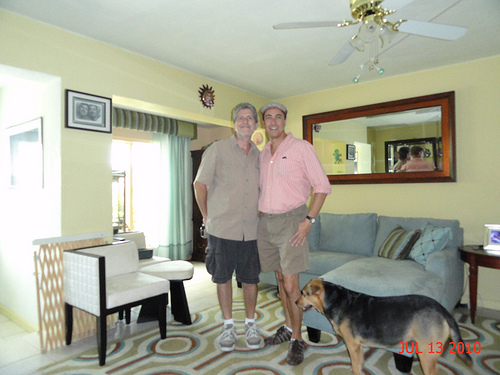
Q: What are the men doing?
A: Posing for a picture.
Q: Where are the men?
A: In a living room.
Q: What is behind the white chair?
A: A child gate.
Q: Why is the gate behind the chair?
A: To make the gate stand.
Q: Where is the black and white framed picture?
A: Hanging on the wall.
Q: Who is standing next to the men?
A: The dog.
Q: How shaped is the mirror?
A: Rectangular.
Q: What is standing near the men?
A: A dog.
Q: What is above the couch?
A: A framed mirror.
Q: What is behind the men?
A: A grey couch.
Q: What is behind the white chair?
A: A baby gate.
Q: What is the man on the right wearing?
A: A pink shirt and tan shorts.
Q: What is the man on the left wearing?
A: A tan shirt and dark brown shorts.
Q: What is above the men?
A: A ceiling fan.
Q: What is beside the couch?
A: An end table.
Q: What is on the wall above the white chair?
A: A framed picture.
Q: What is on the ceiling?
A: A fan.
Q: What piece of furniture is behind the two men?
A: A sofa.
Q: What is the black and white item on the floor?
A: A chair.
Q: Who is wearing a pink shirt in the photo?
A: A man.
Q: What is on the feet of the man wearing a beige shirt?
A: Sneakers.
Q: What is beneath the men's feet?
A: A carpet.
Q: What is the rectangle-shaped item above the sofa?
A: A mirror.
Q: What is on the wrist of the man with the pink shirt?
A: A watch.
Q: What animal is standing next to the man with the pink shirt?
A: A dog.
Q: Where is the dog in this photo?
A: On the right corner.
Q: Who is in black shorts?
A: A man.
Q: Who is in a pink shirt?
A: A man.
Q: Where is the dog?
A: By the couch.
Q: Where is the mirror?
A: On the wall.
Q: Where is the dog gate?
A: Behind the white chair.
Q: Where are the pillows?
A: On the couch.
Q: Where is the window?
A: On the far wall.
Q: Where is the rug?
A: Underneath the people and the furniture.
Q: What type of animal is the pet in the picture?
A: Dog.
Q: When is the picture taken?
A: July 13 2010.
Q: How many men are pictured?
A: Two.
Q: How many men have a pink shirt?
A: One.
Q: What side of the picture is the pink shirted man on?
A: Right.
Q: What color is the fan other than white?
A: Gold.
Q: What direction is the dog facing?
A: Left.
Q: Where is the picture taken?
A: In the living room.